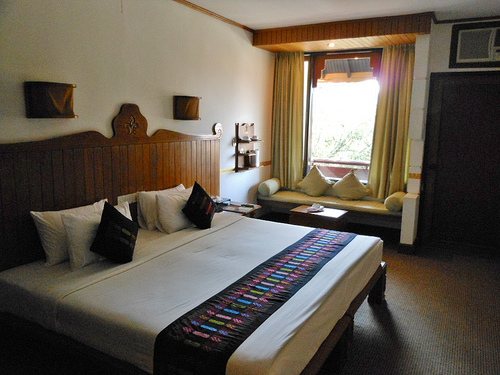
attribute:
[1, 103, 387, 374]
bed — large, wooden, brown, empty, neatly made, big, king size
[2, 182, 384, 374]
sheet — white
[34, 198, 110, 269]
pillow — white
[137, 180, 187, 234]
pillow — white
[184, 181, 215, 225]
pillow — black, decorative, brown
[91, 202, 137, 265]
pillow — black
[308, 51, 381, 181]
window — open, backlit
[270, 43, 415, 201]
curtain — yellow, cream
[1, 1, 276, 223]
wall — white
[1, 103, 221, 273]
headboard — wooden, large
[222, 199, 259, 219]
table — small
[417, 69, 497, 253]
door — dark brown, closet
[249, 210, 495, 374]
carpet — floor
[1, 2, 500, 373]
hotel room — large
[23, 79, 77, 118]
light — brown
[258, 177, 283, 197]
divan — small